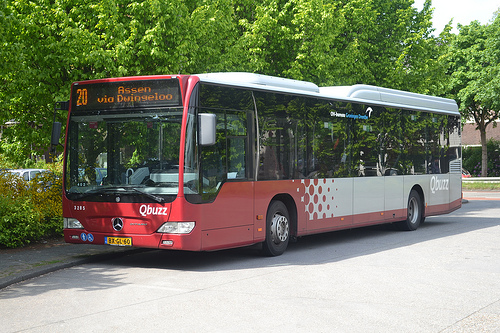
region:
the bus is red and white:
[41, 46, 474, 266]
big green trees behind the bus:
[1, 0, 498, 276]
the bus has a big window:
[63, 99, 188, 209]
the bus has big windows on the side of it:
[197, 102, 459, 187]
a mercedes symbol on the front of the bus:
[106, 210, 131, 236]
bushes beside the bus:
[1, 171, 73, 253]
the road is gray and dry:
[13, 194, 498, 326]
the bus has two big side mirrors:
[37, 106, 229, 154]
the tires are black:
[261, 182, 433, 259]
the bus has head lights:
[58, 213, 196, 241]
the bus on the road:
[63, 69, 467, 250]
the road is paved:
[149, 280, 314, 325]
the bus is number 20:
[63, 75, 498, 247]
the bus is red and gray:
[60, 75, 470, 255]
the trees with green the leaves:
[33, 12, 419, 69]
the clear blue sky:
[448, 0, 480, 20]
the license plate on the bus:
[104, 231, 135, 256]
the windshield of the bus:
[72, 120, 174, 185]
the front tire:
[261, 203, 296, 268]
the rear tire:
[403, 190, 436, 230]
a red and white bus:
[61, 69, 464, 254]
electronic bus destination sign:
[71, 85, 178, 105]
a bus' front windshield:
[66, 113, 180, 202]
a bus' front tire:
[265, 202, 290, 255]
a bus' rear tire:
[399, 189, 423, 229]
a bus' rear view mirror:
[196, 112, 215, 147]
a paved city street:
[0, 194, 497, 329]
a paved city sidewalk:
[2, 230, 129, 287]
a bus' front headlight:
[158, 220, 195, 235]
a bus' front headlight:
[61, 215, 83, 229]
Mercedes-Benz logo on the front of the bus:
[112, 216, 124, 228]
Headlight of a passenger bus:
[155, 220, 195, 233]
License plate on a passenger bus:
[101, 235, 131, 247]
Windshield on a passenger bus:
[62, 111, 184, 203]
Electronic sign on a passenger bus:
[70, 80, 183, 105]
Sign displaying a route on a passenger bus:
[70, 82, 182, 107]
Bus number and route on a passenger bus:
[70, 81, 182, 108]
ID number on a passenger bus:
[72, 205, 85, 209]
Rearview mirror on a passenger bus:
[197, 113, 217, 145]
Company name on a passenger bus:
[427, 174, 450, 194]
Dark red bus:
[64, 71, 459, 268]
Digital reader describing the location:
[65, 78, 183, 110]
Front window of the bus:
[64, 105, 185, 205]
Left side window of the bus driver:
[191, 81, 256, 182]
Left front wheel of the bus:
[261, 192, 296, 258]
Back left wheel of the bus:
[401, 182, 426, 228]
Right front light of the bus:
[61, 215, 82, 233]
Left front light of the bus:
[155, 216, 199, 240]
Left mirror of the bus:
[197, 108, 218, 148]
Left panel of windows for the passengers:
[258, 86, 462, 178]